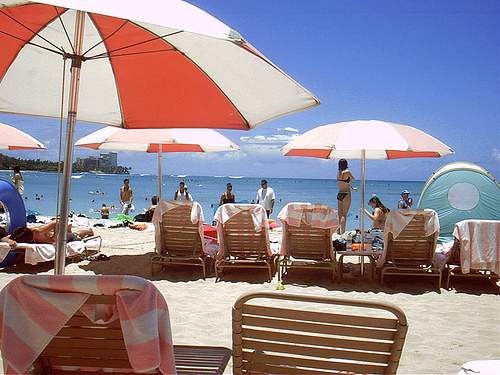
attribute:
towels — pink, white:
[279, 198, 335, 260]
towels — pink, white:
[0, 271, 176, 373]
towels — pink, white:
[430, 218, 498, 279]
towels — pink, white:
[2, 239, 85, 264]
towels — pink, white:
[152, 194, 217, 257]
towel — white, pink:
[6, 259, 158, 373]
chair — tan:
[151, 203, 206, 273]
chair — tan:
[214, 203, 276, 280]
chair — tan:
[280, 202, 338, 279]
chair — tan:
[368, 209, 442, 286]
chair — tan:
[448, 223, 498, 287]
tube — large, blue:
[0, 182, 37, 249]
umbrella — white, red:
[270, 97, 464, 202]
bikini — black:
[337, 169, 352, 201]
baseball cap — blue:
[402, 187, 409, 194]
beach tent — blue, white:
[407, 159, 497, 239]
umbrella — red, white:
[280, 106, 461, 165]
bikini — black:
[339, 189, 342, 199]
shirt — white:
[257, 186, 272, 210]